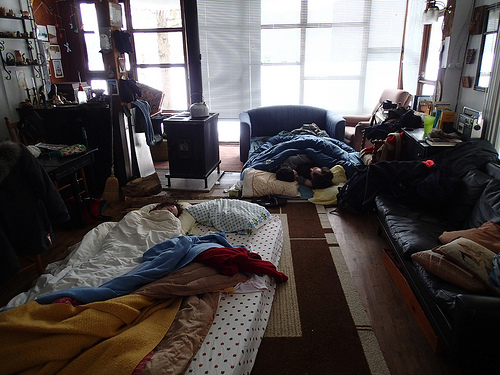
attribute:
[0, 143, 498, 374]
floor — hardwood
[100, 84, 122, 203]
broom — straw, leaning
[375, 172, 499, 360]
couch — black, vinyl, leather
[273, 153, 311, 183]
person — sleeping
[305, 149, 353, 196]
person — sleeping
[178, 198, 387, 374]
rug — brown, cream, maroon, beige, large, tan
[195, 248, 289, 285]
blanket — red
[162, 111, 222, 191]
stove — wood burning, black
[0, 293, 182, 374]
blanket — gold, butterscotch colored, tan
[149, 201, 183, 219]
person — sleeping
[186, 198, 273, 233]
pillow — standard size, polka dotted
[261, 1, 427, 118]
windows — glass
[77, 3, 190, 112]
windows — glass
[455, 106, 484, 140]
radio — compact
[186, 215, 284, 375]
sheet — polka dotted, white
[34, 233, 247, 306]
blanket — blue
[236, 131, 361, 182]
blanket — blue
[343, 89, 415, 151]
chair — light brown